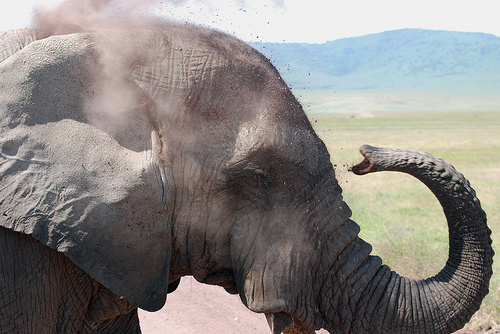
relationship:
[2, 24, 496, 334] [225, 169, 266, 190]
elephant has right eye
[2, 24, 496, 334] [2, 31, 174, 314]
elephant has ear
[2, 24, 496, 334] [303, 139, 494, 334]
elephant has trunk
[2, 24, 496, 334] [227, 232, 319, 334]
elephant has mouth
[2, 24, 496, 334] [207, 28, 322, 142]
elephant has forehead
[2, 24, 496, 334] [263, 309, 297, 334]
elephant has tush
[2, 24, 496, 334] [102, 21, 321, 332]
elephant has head